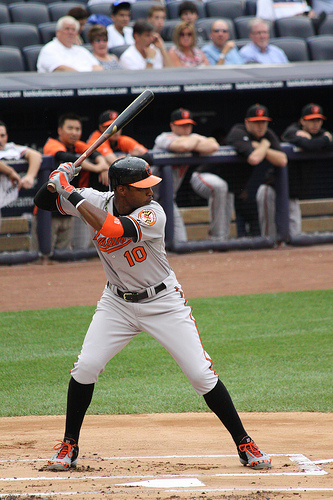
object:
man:
[46, 155, 271, 469]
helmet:
[107, 155, 163, 190]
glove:
[47, 168, 86, 209]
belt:
[106, 281, 168, 303]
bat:
[46, 89, 155, 192]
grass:
[2, 288, 331, 416]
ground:
[2, 243, 330, 498]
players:
[225, 102, 289, 247]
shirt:
[33, 176, 173, 291]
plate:
[115, 471, 204, 493]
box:
[0, 452, 328, 480]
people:
[37, 15, 104, 73]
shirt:
[36, 36, 101, 73]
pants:
[68, 271, 219, 395]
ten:
[123, 245, 148, 268]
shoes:
[236, 436, 271, 468]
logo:
[136, 209, 157, 229]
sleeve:
[121, 203, 164, 244]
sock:
[201, 377, 248, 447]